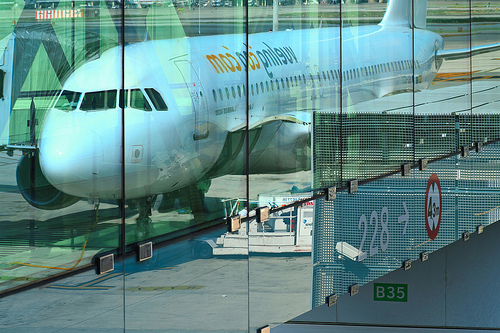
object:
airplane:
[6, 0, 500, 241]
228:
[357, 205, 389, 261]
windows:
[211, 89, 217, 103]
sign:
[424, 173, 442, 240]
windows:
[124, 0, 249, 333]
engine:
[16, 150, 82, 210]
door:
[173, 59, 209, 141]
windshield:
[79, 90, 106, 111]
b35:
[375, 285, 405, 299]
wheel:
[131, 223, 154, 241]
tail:
[377, 0, 500, 61]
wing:
[197, 110, 315, 182]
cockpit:
[38, 37, 210, 199]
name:
[205, 41, 299, 78]